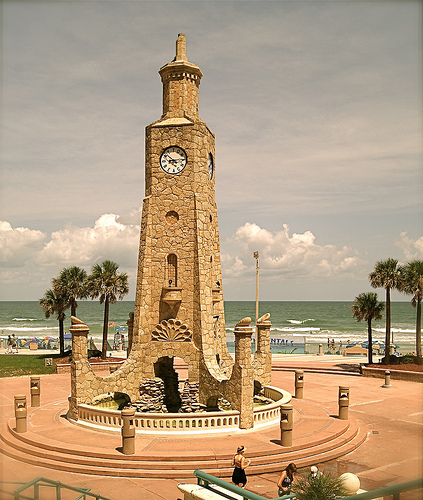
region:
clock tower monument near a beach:
[56, 30, 283, 414]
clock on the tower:
[155, 137, 188, 182]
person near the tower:
[226, 440, 251, 491]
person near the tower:
[274, 455, 301, 493]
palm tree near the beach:
[355, 290, 375, 369]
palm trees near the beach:
[369, 248, 422, 355]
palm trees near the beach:
[38, 260, 124, 347]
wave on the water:
[285, 311, 314, 331]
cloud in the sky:
[241, 214, 305, 255]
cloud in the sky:
[92, 208, 134, 252]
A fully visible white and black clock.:
[156, 145, 188, 175]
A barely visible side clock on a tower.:
[207, 151, 212, 180]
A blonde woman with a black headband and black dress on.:
[232, 444, 251, 486]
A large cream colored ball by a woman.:
[336, 472, 360, 497]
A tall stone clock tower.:
[125, 31, 227, 368]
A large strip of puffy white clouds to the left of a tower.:
[2, 218, 142, 271]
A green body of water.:
[0, 301, 418, 327]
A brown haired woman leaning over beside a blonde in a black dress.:
[274, 462, 296, 495]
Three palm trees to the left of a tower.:
[38, 260, 131, 354]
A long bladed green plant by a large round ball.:
[284, 468, 349, 498]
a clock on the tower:
[159, 145, 188, 174]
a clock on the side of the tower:
[205, 153, 215, 179]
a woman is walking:
[230, 444, 254, 484]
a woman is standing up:
[277, 461, 299, 493]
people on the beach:
[326, 336, 350, 349]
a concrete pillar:
[119, 409, 135, 453]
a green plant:
[293, 470, 346, 495]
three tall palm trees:
[350, 260, 421, 360]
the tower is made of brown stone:
[68, 32, 268, 422]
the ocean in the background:
[0, 297, 420, 335]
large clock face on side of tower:
[153, 138, 194, 175]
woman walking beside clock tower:
[213, 437, 257, 496]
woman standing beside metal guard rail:
[272, 456, 307, 498]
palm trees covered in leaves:
[26, 256, 126, 361]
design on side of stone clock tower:
[145, 315, 195, 350]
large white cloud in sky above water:
[225, 218, 358, 288]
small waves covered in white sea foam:
[276, 322, 344, 339]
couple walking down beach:
[5, 329, 24, 356]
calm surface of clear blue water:
[266, 298, 353, 318]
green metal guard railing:
[9, 467, 115, 498]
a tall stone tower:
[130, 40, 233, 396]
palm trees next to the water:
[352, 257, 415, 340]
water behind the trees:
[9, 296, 419, 335]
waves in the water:
[273, 310, 329, 335]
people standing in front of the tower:
[225, 443, 290, 497]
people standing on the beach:
[326, 335, 350, 350]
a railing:
[193, 462, 254, 495]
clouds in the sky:
[226, 201, 400, 292]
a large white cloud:
[231, 228, 322, 270]